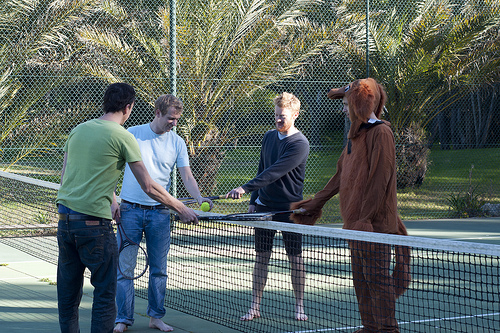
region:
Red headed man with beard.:
[229, 78, 310, 323]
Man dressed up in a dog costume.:
[291, 68, 420, 323]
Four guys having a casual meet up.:
[52, 70, 419, 327]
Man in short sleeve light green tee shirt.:
[53, 78, 192, 330]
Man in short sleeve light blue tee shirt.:
[119, 85, 207, 329]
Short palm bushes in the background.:
[3, 9, 495, 229]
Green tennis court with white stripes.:
[3, 216, 498, 329]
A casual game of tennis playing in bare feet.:
[51, 74, 428, 328]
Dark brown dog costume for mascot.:
[288, 77, 415, 332]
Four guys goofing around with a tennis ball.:
[52, 76, 413, 325]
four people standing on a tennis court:
[37, 46, 436, 331]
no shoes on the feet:
[228, 296, 320, 325]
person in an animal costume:
[294, 63, 430, 331]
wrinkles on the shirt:
[74, 159, 117, 210]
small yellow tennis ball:
[197, 200, 214, 212]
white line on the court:
[294, 298, 499, 331]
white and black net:
[0, 168, 496, 330]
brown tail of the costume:
[392, 211, 420, 302]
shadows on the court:
[103, 286, 483, 328]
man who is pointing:
[218, 89, 318, 328]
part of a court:
[162, 294, 187, 327]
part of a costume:
[361, 160, 386, 203]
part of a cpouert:
[178, 300, 199, 327]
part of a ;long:
[60, 237, 92, 285]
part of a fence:
[187, 63, 234, 123]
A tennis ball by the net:
[198, 203, 217, 210]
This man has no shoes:
[242, 301, 316, 320]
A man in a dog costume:
[310, 82, 406, 331]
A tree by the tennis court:
[390, 30, 477, 181]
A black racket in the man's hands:
[111, 214, 148, 279]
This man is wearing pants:
[55, 215, 115, 327]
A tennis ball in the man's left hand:
[196, 193, 216, 211]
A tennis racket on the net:
[227, 210, 304, 218]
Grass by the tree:
[437, 148, 494, 171]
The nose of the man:
[171, 116, 178, 125]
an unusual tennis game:
[60, 53, 430, 328]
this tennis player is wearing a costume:
[284, 68, 416, 330]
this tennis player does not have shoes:
[208, 81, 318, 323]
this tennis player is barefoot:
[115, 87, 194, 329]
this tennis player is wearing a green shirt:
[46, 71, 163, 332]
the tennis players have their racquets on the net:
[178, 183, 295, 243]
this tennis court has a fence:
[31, 43, 348, 173]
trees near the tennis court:
[8, 3, 457, 120]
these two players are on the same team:
[203, 76, 414, 332]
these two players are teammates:
[55, 81, 212, 326]